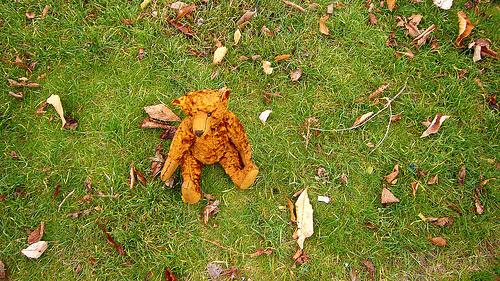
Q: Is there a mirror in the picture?
A: No, there are no mirrors.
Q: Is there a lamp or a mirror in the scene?
A: No, there are no mirrors or lamps.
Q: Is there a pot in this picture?
A: No, there are no pots.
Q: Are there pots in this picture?
A: No, there are no pots.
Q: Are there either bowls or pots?
A: No, there are no pots or bowls.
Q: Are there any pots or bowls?
A: No, there are no pots or bowls.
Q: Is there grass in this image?
A: Yes, there is grass.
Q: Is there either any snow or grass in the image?
A: Yes, there is grass.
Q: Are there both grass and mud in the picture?
A: No, there is grass but no mud.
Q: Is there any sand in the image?
A: No, there is no sand.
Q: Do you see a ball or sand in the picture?
A: No, there are no sand or balls.